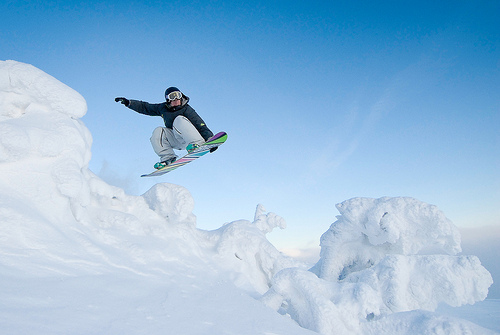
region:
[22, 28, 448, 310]
this is on a mountain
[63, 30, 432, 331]
this is a slope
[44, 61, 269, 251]
this is a snowboarder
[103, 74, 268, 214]
the person is in mid air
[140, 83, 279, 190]
the person is doing a trick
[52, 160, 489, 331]
the snow is piled up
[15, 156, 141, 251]
the ground is covered in deep snow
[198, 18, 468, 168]
the sky is mostly clear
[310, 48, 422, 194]
the clouds are very thin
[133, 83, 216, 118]
the snowboarder has goggles on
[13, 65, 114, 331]
Big rocks covered with snow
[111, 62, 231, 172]
Different color ski board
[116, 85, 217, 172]
A man on the ski board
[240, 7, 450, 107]
Clean and neat sky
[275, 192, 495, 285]
Clouds in the sky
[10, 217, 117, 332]
The snow is white in color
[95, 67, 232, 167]
A man wearing black jacket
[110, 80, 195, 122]
A black gloves in the man's hand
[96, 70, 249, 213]
A man in the air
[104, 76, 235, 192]
A man playing tricks with ski board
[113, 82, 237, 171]
the man is in the air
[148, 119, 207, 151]
the pants are white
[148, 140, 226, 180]
the board is red and blue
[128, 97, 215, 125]
the jacket is blue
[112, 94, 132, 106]
the glove is black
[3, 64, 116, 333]
the snow is white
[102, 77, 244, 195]
the man is snow surfing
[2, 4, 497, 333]
the season is winter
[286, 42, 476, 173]
the sky has no clouds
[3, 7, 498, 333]
the photo was taken during the day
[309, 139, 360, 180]
part of a cloud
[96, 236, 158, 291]
part of a cloud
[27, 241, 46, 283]
part of a snkiw